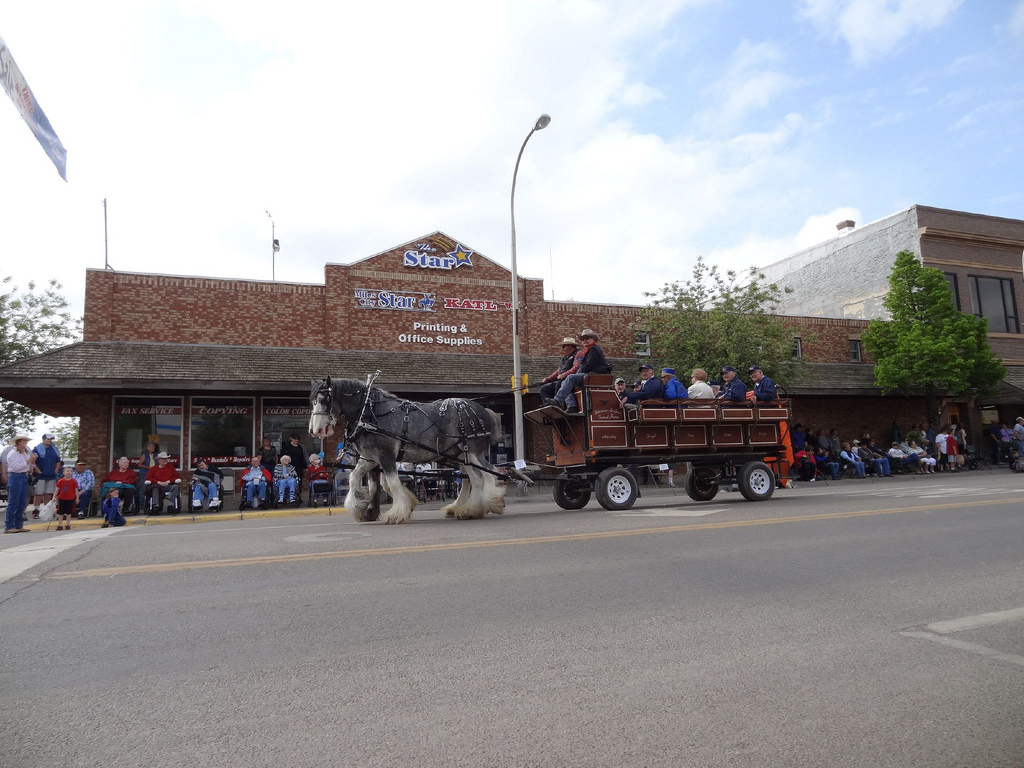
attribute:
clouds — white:
[49, 7, 378, 173]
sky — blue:
[4, 4, 998, 229]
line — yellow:
[168, 547, 342, 580]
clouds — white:
[4, 10, 934, 263]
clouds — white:
[207, 100, 245, 133]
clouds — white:
[318, 165, 410, 230]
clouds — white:
[364, 70, 460, 144]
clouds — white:
[596, 62, 667, 110]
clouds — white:
[639, 213, 694, 252]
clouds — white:
[728, 39, 827, 134]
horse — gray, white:
[313, 372, 503, 528]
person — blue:
[624, 358, 669, 403]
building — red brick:
[8, 213, 926, 467]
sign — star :
[8, 213, 926, 467]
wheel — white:
[595, 460, 640, 509]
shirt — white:
[6, 431, 41, 484]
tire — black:
[582, 467, 658, 519]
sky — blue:
[803, 36, 925, 188]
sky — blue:
[792, 73, 978, 207]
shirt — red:
[92, 464, 196, 501]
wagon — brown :
[534, 371, 809, 499]